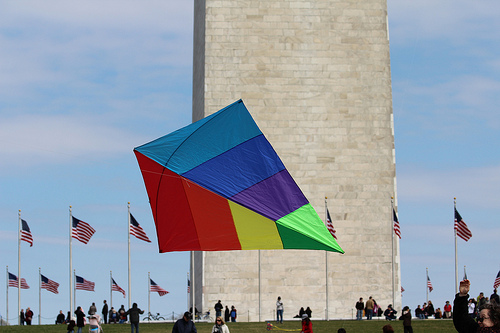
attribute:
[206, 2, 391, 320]
exterior — stone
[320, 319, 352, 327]
grass — part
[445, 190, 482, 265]
flag — red, white, blue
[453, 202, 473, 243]
flag — American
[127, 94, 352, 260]
kite — colorful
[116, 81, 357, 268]
flag — diamond shaped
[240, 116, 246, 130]
kite — edge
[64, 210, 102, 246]
flag — red, white, blue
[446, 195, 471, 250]
flag — red, white, and blue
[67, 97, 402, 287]
kite — rainbow colored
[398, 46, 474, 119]
sky — blue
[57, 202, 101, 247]
flag — red, white, blue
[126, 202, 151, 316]
flag — red, blue